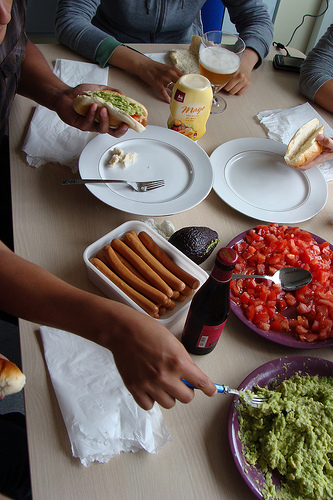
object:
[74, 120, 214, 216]
plate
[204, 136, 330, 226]
plate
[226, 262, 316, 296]
spoon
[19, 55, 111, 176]
paper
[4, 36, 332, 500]
table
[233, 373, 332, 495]
food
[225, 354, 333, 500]
plate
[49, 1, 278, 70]
blouse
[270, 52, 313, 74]
phone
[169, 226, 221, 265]
avocado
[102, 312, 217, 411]
hand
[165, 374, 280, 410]
fork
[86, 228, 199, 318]
franks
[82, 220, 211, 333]
dish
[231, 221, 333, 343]
tomato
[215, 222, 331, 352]
plate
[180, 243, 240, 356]
bottle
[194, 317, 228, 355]
label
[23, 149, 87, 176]
edge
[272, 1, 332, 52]
cable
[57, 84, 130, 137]
hand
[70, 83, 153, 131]
hotdog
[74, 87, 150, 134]
guacamole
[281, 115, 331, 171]
bun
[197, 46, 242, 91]
beer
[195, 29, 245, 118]
glass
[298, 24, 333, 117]
person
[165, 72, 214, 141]
jar